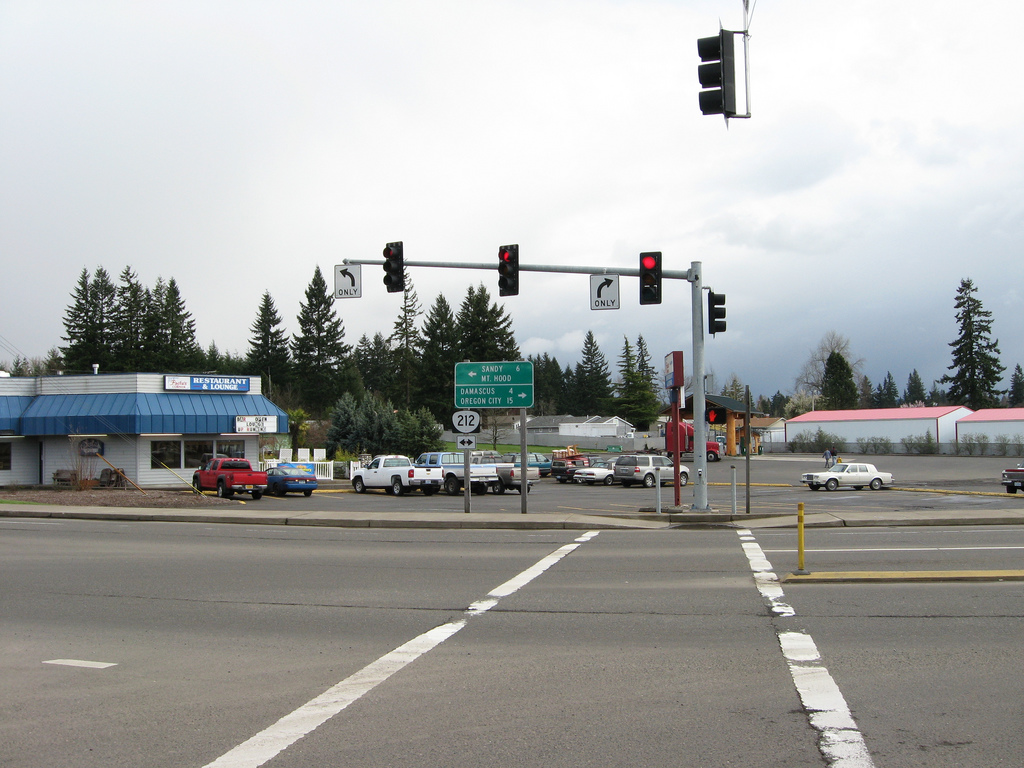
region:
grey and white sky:
[345, 26, 620, 216]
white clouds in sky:
[175, 6, 643, 155]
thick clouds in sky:
[108, 18, 780, 287]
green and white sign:
[444, 377, 552, 420]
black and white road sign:
[447, 395, 490, 476]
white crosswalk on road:
[108, 512, 742, 728]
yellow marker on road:
[716, 471, 847, 623]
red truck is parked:
[178, 430, 256, 535]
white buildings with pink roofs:
[778, 399, 1022, 456]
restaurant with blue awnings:
[0, 372, 294, 499]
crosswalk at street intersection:
[196, 514, 890, 767]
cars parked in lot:
[188, 443, 695, 502]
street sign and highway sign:
[449, 353, 539, 518]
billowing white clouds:
[513, 130, 1016, 397]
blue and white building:
[18, 353, 293, 515]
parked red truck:
[198, 445, 279, 510]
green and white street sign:
[444, 344, 552, 431]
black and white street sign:
[574, 267, 639, 335]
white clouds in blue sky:
[363, 99, 446, 153]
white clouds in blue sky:
[258, 104, 358, 168]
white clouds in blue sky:
[887, 153, 954, 201]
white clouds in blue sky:
[552, 65, 604, 124]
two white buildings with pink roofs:
[781, 407, 1022, 456]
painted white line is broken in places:
[733, 524, 874, 763]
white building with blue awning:
[0, 363, 291, 488]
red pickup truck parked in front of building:
[0, 365, 291, 502]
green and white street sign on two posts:
[451, 356, 537, 513]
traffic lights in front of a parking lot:
[166, 239, 1021, 522]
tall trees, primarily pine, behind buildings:
[0, 265, 1022, 493]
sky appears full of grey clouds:
[0, 2, 1018, 407]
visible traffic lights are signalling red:
[332, 242, 726, 514]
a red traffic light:
[319, 222, 706, 318]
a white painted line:
[705, 503, 822, 712]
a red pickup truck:
[186, 429, 269, 505]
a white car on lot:
[808, 449, 897, 503]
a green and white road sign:
[448, 344, 553, 418]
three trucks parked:
[344, 421, 534, 510]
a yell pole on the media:
[786, 478, 821, 592]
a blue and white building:
[8, 372, 294, 490]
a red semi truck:
[664, 421, 728, 464]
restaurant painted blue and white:
[2, 361, 291, 491]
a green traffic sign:
[454, 358, 535, 412]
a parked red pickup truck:
[193, 454, 271, 497]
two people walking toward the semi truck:
[822, 444, 841, 468]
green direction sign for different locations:
[450, 358, 539, 515]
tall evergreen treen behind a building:
[949, 271, 1008, 401]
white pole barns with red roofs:
[782, 409, 1023, 444]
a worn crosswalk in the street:
[162, 518, 872, 765]